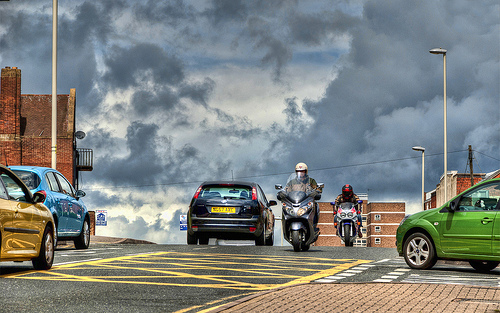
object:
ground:
[0, 238, 500, 313]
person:
[284, 161, 322, 196]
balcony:
[75, 148, 94, 172]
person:
[330, 179, 364, 238]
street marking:
[0, 250, 369, 312]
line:
[6, 249, 372, 294]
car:
[395, 177, 500, 269]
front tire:
[287, 221, 305, 251]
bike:
[328, 200, 364, 247]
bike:
[272, 182, 324, 251]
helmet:
[294, 162, 309, 174]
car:
[185, 181, 277, 247]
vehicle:
[0, 162, 59, 270]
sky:
[0, 0, 500, 245]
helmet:
[341, 184, 354, 197]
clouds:
[0, 0, 499, 245]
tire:
[397, 228, 438, 272]